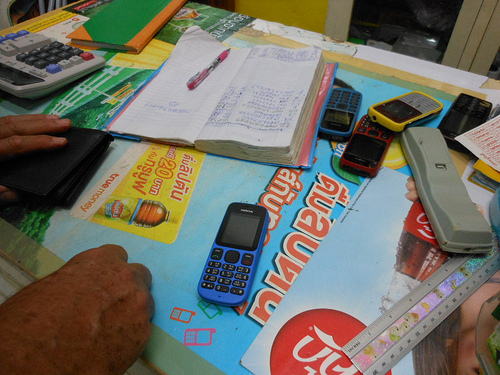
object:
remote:
[397, 126, 494, 253]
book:
[67, 0, 187, 55]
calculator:
[0, 30, 107, 102]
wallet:
[0, 127, 113, 211]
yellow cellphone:
[366, 90, 445, 133]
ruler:
[340, 229, 500, 374]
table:
[0, 0, 497, 375]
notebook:
[65, 0, 187, 55]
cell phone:
[197, 201, 270, 307]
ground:
[189, 0, 500, 84]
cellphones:
[437, 92, 493, 155]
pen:
[186, 47, 233, 89]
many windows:
[219, 100, 483, 248]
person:
[0, 113, 156, 373]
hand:
[1, 244, 157, 373]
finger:
[99, 243, 129, 263]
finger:
[128, 262, 153, 289]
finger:
[148, 292, 155, 316]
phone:
[196, 201, 271, 307]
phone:
[339, 114, 395, 179]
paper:
[451, 114, 500, 170]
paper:
[108, 24, 250, 143]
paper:
[194, 44, 322, 149]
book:
[104, 24, 339, 169]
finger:
[0, 114, 60, 122]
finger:
[0, 118, 72, 138]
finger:
[0, 134, 67, 158]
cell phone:
[317, 87, 363, 142]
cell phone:
[339, 114, 394, 179]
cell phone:
[366, 90, 444, 133]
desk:
[0, 0, 500, 372]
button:
[46, 63, 62, 74]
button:
[58, 59, 72, 69]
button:
[69, 55, 83, 65]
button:
[34, 59, 49, 69]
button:
[46, 55, 61, 64]